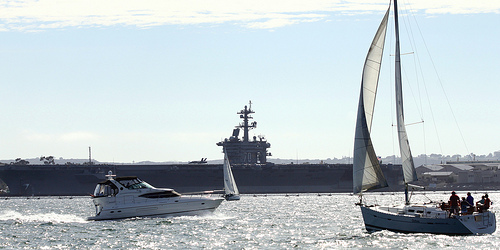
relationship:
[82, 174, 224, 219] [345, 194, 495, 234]
boat nearer to ship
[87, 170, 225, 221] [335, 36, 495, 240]
boat cruising by sailboat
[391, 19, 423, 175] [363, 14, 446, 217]
rope ladder on top of mast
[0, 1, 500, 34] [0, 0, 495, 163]
clouds in sky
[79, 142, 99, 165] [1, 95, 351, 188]
crane on ship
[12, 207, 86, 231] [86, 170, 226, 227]
wake left by motor boat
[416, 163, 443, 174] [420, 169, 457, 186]
building on building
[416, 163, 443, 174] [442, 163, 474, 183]
building on building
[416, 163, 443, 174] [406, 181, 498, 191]
building on shore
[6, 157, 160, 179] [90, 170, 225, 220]
hill behind ship